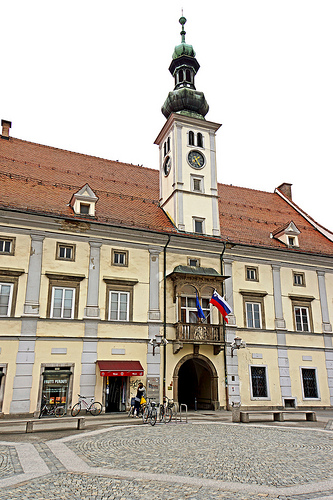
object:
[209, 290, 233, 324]
flag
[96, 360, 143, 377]
awning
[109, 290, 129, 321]
window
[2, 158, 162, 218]
roof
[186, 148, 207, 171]
clock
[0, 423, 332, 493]
road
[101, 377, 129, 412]
door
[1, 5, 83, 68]
sky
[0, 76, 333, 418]
building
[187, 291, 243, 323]
flags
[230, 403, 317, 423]
bench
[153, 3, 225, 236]
tower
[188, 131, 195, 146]
windows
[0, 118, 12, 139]
chimney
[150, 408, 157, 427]
wheel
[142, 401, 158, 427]
bicycle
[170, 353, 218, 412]
tunnel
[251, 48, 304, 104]
clouds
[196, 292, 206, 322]
flag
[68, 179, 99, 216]
window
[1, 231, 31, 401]
wall